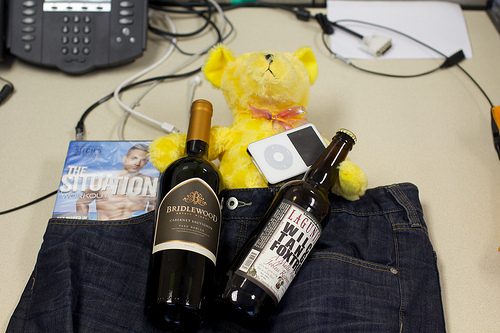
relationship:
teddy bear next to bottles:
[155, 48, 363, 199] [140, 99, 355, 328]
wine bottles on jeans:
[140, 99, 355, 328] [6, 183, 444, 331]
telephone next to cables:
[5, 0, 146, 75] [76, 6, 467, 134]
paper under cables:
[326, 2, 467, 61] [76, 6, 467, 134]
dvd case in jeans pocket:
[53, 136, 167, 224] [50, 208, 151, 286]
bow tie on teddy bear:
[248, 107, 305, 129] [155, 48, 363, 199]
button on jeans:
[224, 196, 242, 212] [6, 183, 444, 331]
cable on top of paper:
[323, 18, 396, 61] [326, 2, 467, 61]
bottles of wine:
[140, 99, 355, 328] [144, 99, 226, 328]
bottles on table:
[140, 99, 355, 328] [10, 9, 486, 332]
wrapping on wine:
[180, 97, 214, 146] [144, 99, 226, 328]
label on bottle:
[150, 181, 218, 264] [144, 99, 226, 328]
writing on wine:
[165, 203, 218, 222] [144, 99, 226, 328]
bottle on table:
[220, 126, 359, 320] [10, 9, 486, 332]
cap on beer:
[336, 130, 360, 143] [220, 126, 359, 320]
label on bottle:
[234, 201, 322, 306] [220, 126, 359, 320]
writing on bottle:
[266, 210, 320, 273] [220, 126, 359, 320]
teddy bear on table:
[155, 48, 363, 199] [10, 9, 486, 332]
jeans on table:
[6, 183, 444, 331] [10, 9, 486, 332]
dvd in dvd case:
[53, 136, 167, 224] [53, 136, 167, 224]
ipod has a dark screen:
[245, 125, 326, 185] [289, 124, 326, 170]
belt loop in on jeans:
[387, 185, 422, 229] [6, 183, 444, 331]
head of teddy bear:
[209, 41, 319, 115] [155, 48, 363, 199]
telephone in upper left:
[5, 0, 146, 75] [0, 1, 187, 112]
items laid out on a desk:
[41, 48, 453, 332] [10, 9, 486, 332]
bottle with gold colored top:
[144, 99, 226, 328] [180, 97, 214, 146]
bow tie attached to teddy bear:
[248, 107, 305, 129] [155, 48, 363, 199]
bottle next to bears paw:
[220, 126, 359, 320] [327, 160, 371, 205]